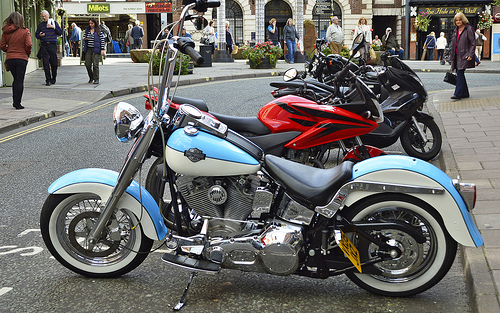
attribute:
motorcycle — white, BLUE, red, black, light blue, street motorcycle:
[32, 4, 479, 312]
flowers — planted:
[245, 38, 277, 68]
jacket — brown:
[449, 20, 476, 66]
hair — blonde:
[453, 10, 471, 30]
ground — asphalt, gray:
[6, 57, 460, 309]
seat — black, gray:
[266, 148, 356, 197]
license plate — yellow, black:
[329, 230, 368, 272]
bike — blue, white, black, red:
[35, 5, 493, 292]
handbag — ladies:
[440, 65, 458, 92]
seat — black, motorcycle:
[263, 151, 359, 201]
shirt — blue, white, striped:
[78, 28, 110, 53]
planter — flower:
[245, 44, 278, 72]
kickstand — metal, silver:
[164, 267, 214, 309]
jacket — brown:
[0, 27, 32, 60]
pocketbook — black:
[440, 66, 463, 89]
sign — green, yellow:
[83, 2, 116, 15]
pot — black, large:
[247, 46, 277, 73]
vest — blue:
[84, 30, 104, 52]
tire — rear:
[327, 178, 469, 309]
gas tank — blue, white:
[204, 185, 237, 206]